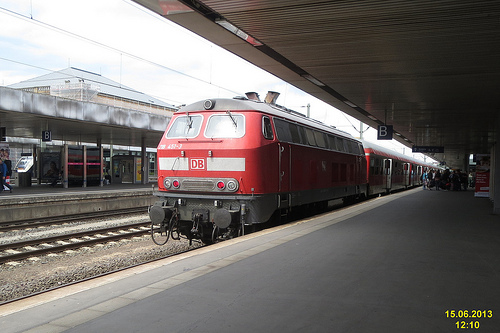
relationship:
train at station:
[135, 87, 460, 249] [128, 2, 498, 331]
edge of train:
[251, 192, 369, 220] [123, 100, 374, 244]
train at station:
[135, 87, 460, 249] [61, 24, 498, 305]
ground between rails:
[0, 209, 218, 306] [0, 224, 166, 267]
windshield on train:
[200, 108, 247, 141] [135, 87, 460, 249]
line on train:
[156, 153, 247, 173] [159, 90, 412, 224]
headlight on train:
[164, 170, 239, 192] [135, 87, 460, 249]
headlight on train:
[164, 176, 238, 192] [146, 90, 446, 247]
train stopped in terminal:
[148, 92, 449, 246] [340, 99, 485, 252]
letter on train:
[187, 152, 205, 174] [146, 90, 446, 247]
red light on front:
[214, 179, 226, 191] [148, 88, 264, 237]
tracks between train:
[2, 212, 137, 268] [100, 87, 431, 236]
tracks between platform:
[2, 212, 137, 268] [14, 152, 137, 232]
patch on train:
[159, 157, 188, 169] [146, 90, 446, 247]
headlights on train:
[161, 172, 239, 194] [146, 90, 446, 247]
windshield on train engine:
[165, 114, 246, 139] [127, 73, 381, 273]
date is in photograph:
[445, 310, 493, 317] [0, 0, 496, 330]